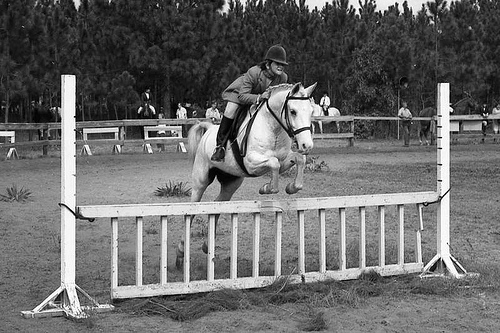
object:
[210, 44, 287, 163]
girl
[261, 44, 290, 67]
helmet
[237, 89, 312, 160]
reins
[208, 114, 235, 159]
boots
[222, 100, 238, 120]
pants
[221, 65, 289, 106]
coat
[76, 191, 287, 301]
fence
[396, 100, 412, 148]
man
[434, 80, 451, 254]
pole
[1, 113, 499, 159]
fence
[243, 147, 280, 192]
leg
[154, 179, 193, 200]
plant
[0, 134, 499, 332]
ground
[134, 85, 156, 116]
person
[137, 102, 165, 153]
horse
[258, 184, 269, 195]
hoof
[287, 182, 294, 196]
hoof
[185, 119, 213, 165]
tail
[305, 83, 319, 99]
ear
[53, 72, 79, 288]
pole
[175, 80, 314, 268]
horse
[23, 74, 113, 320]
post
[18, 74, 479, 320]
gate